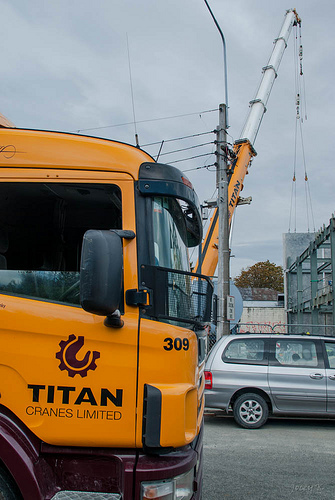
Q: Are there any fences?
A: No, there are no fences.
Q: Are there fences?
A: No, there are no fences.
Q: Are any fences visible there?
A: No, there are no fences.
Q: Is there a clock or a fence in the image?
A: No, there are no fences or clocks.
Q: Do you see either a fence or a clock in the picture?
A: No, there are no fences or clocks.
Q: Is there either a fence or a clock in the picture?
A: No, there are no fences or clocks.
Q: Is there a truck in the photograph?
A: Yes, there is a truck.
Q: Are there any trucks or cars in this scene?
A: Yes, there is a truck.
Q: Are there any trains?
A: No, there are no trains.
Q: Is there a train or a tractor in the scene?
A: No, there are no trains or tractors.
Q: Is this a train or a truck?
A: This is a truck.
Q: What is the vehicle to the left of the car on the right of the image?
A: The vehicle is a truck.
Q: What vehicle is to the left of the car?
A: The vehicle is a truck.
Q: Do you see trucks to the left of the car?
A: Yes, there is a truck to the left of the car.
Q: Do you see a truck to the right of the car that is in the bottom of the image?
A: No, the truck is to the left of the car.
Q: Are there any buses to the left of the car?
A: No, there is a truck to the left of the car.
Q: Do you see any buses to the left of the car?
A: No, there is a truck to the left of the car.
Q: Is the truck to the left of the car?
A: Yes, the truck is to the left of the car.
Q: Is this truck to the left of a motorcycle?
A: No, the truck is to the left of the car.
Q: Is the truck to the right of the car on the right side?
A: No, the truck is to the left of the car.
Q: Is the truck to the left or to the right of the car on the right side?
A: The truck is to the left of the car.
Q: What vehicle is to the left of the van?
A: The vehicle is a truck.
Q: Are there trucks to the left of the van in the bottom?
A: Yes, there is a truck to the left of the van.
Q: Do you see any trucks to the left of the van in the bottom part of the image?
A: Yes, there is a truck to the left of the van.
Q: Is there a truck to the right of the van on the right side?
A: No, the truck is to the left of the van.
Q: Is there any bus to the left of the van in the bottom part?
A: No, there is a truck to the left of the van.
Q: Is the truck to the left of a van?
A: Yes, the truck is to the left of a van.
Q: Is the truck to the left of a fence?
A: No, the truck is to the left of a van.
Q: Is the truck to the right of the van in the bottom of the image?
A: No, the truck is to the left of the van.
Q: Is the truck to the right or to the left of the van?
A: The truck is to the left of the van.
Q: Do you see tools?
A: No, there are no tools.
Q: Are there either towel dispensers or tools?
A: No, there are no tools or towel dispensers.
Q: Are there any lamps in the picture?
A: No, there are no lamps.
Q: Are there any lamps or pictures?
A: No, there are no lamps or pictures.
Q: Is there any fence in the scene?
A: No, there are no fences.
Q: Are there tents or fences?
A: No, there are no fences or tents.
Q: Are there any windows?
A: Yes, there is a window.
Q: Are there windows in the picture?
A: Yes, there is a window.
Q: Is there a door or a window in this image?
A: Yes, there is a window.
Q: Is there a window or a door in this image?
A: Yes, there is a window.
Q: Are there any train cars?
A: No, there are no train cars.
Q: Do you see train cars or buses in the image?
A: No, there are no train cars or buses.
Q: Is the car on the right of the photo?
A: Yes, the car is on the right of the image.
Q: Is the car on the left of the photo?
A: No, the car is on the right of the image.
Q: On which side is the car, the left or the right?
A: The car is on the right of the image.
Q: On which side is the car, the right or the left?
A: The car is on the right of the image.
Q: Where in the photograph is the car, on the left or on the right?
A: The car is on the right of the image.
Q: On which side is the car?
A: The car is on the right of the image.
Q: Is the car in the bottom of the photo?
A: Yes, the car is in the bottom of the image.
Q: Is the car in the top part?
A: No, the car is in the bottom of the image.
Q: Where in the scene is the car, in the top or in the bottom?
A: The car is in the bottom of the image.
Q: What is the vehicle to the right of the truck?
A: The vehicle is a car.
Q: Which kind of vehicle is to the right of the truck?
A: The vehicle is a car.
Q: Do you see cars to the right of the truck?
A: Yes, there is a car to the right of the truck.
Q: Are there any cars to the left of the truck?
A: No, the car is to the right of the truck.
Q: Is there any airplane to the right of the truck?
A: No, there is a car to the right of the truck.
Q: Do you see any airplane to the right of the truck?
A: No, there is a car to the right of the truck.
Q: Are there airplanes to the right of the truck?
A: No, there is a car to the right of the truck.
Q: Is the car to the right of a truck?
A: Yes, the car is to the right of a truck.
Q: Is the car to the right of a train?
A: No, the car is to the right of a truck.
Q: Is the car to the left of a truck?
A: No, the car is to the right of a truck.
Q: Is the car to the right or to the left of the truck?
A: The car is to the right of the truck.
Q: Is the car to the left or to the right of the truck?
A: The car is to the right of the truck.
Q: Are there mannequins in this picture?
A: No, there are no mannequins.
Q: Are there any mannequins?
A: No, there are no mannequins.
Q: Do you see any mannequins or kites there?
A: No, there are no mannequins or kites.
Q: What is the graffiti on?
A: The graffiti is on the wall.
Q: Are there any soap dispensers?
A: No, there are no soap dispensers.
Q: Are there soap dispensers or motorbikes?
A: No, there are no soap dispensers or motorbikes.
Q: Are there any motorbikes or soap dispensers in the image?
A: No, there are no soap dispensers or motorbikes.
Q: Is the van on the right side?
A: Yes, the van is on the right of the image.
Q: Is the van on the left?
A: No, the van is on the right of the image.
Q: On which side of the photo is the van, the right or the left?
A: The van is on the right of the image.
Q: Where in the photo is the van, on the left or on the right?
A: The van is on the right of the image.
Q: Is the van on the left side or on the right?
A: The van is on the right of the image.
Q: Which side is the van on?
A: The van is on the right of the image.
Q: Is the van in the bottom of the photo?
A: Yes, the van is in the bottom of the image.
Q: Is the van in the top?
A: No, the van is in the bottom of the image.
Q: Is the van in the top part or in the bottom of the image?
A: The van is in the bottom of the image.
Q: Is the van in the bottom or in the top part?
A: The van is in the bottom of the image.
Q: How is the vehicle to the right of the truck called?
A: The vehicle is a van.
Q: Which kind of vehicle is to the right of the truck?
A: The vehicle is a van.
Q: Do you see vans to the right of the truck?
A: Yes, there is a van to the right of the truck.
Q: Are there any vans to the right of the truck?
A: Yes, there is a van to the right of the truck.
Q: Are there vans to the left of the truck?
A: No, the van is to the right of the truck.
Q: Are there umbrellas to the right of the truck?
A: No, there is a van to the right of the truck.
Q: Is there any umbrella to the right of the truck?
A: No, there is a van to the right of the truck.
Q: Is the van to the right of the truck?
A: Yes, the van is to the right of the truck.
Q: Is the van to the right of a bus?
A: No, the van is to the right of the truck.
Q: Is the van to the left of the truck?
A: No, the van is to the right of the truck.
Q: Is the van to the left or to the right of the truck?
A: The van is to the right of the truck.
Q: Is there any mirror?
A: Yes, there is a mirror.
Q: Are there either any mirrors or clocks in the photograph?
A: Yes, there is a mirror.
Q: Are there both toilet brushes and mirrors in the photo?
A: No, there is a mirror but no toilet brushes.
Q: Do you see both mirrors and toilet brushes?
A: No, there is a mirror but no toilet brushes.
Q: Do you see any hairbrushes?
A: No, there are no hairbrushes.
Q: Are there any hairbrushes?
A: No, there are no hairbrushes.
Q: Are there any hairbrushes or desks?
A: No, there are no hairbrushes or desks.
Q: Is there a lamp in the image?
A: No, there are no lamps.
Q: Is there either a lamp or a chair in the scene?
A: No, there are no lamps or chairs.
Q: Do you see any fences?
A: No, there are no fences.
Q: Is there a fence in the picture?
A: No, there are no fences.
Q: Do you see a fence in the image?
A: No, there are no fences.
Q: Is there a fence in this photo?
A: No, there are no fences.